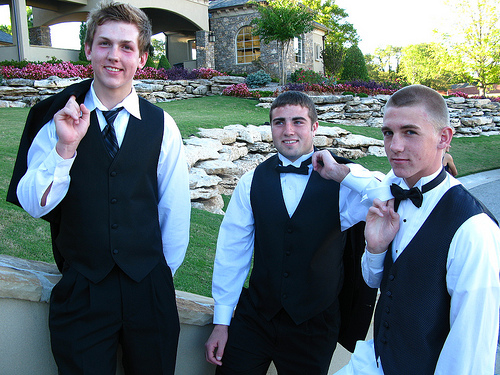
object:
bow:
[390, 183, 424, 209]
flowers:
[247, 1, 350, 45]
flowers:
[352, 80, 479, 100]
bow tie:
[390, 167, 447, 209]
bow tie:
[274, 147, 317, 175]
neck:
[278, 144, 315, 162]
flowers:
[273, 67, 500, 102]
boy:
[15, 2, 191, 375]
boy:
[204, 89, 387, 375]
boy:
[331, 84, 498, 375]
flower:
[222, 83, 251, 97]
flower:
[147, 67, 168, 80]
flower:
[312, 82, 339, 92]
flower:
[342, 82, 358, 92]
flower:
[1, 63, 87, 79]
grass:
[0, 94, 497, 300]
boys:
[14, 4, 500, 375]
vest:
[372, 184, 499, 374]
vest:
[248, 153, 348, 325]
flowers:
[162, 64, 222, 80]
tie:
[101, 107, 123, 160]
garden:
[0, 69, 497, 326]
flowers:
[0, 60, 261, 98]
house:
[208, 0, 330, 85]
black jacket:
[5, 78, 93, 209]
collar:
[80, 80, 142, 120]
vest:
[55, 95, 164, 283]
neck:
[403, 163, 443, 190]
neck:
[93, 75, 132, 106]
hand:
[53, 95, 90, 144]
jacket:
[6, 79, 94, 223]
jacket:
[330, 153, 375, 354]